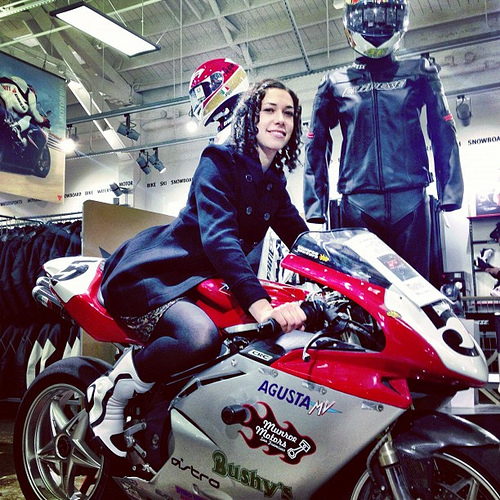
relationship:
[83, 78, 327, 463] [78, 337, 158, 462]
girl wearing boot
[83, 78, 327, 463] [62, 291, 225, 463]
girl has leg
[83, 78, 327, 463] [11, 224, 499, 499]
girl on a bike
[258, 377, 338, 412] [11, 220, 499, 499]
brand on bike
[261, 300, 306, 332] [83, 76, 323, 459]
hand of man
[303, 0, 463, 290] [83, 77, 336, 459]
outfit next to lady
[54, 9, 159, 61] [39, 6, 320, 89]
fixture hanging from ceiling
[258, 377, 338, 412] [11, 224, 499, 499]
brand on bike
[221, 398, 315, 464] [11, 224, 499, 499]
brand on bike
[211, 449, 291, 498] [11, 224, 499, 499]
brand on bike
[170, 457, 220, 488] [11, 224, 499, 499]
brand on bike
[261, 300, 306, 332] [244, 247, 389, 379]
hand on handlebar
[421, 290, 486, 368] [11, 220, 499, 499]
5 on bike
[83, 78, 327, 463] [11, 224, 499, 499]
girl on bike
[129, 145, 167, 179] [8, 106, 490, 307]
light fixture pointed towards wall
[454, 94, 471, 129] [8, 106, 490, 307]
light fixture pointed towards wall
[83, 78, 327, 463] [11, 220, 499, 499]
girl on bike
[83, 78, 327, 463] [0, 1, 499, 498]
girl in store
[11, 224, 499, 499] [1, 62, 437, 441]
bike in store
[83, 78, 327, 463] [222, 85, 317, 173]
girl with hair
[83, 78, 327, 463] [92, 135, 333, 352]
girl wearing jacket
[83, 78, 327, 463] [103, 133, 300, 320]
girl wearing jacket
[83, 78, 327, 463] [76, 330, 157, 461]
girl wearing boots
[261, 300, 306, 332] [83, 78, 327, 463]
hand of girl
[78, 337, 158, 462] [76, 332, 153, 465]
boot on foot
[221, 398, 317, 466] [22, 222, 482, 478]
brand on bike